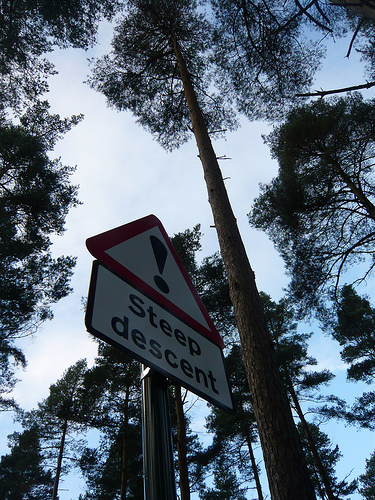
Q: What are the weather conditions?
A: It is clear.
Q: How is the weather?
A: It is clear.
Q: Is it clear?
A: Yes, it is clear.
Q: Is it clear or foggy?
A: It is clear.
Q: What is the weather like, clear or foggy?
A: It is clear.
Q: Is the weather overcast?
A: No, it is clear.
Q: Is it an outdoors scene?
A: Yes, it is outdoors.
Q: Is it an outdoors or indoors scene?
A: It is outdoors.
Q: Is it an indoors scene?
A: No, it is outdoors.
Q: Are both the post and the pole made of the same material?
A: Yes, both the post and the pole are made of metal.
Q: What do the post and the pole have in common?
A: The material, both the post and the pole are metallic.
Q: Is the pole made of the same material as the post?
A: Yes, both the pole and the post are made of metal.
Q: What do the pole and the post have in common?
A: The material, both the pole and the post are metallic.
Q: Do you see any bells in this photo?
A: No, there are no bells.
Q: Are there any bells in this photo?
A: No, there are no bells.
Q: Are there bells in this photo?
A: No, there are no bells.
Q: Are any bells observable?
A: No, there are no bells.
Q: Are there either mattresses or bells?
A: No, there are no bells or mattresses.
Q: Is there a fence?
A: No, there are no fences.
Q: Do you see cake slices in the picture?
A: No, there are no cake slices.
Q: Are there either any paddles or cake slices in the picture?
A: No, there are no cake slices or paddles.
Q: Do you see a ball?
A: No, there are no balls.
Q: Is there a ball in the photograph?
A: No, there are no balls.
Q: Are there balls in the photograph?
A: No, there are no balls.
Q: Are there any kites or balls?
A: No, there are no balls or kites.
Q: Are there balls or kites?
A: No, there are no balls or kites.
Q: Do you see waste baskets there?
A: No, there are no waste baskets.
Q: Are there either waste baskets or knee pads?
A: No, there are no waste baskets or knee pads.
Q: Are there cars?
A: No, there are no cars.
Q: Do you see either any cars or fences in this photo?
A: No, there are no cars or fences.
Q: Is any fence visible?
A: No, there are no fences.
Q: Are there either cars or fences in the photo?
A: No, there are no fences or cars.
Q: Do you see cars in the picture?
A: No, there are no cars.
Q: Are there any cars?
A: No, there are no cars.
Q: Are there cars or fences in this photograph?
A: No, there are no cars or fences.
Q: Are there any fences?
A: No, there are no fences.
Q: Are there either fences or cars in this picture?
A: No, there are no fences or cars.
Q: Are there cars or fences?
A: No, there are no fences or cars.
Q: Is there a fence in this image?
A: No, there are no fences.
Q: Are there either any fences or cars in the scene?
A: No, there are no fences or cars.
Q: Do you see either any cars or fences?
A: No, there are no cars or fences.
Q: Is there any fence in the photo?
A: No, there are no fences.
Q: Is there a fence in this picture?
A: No, there are no fences.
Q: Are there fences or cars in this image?
A: No, there are no fences or cars.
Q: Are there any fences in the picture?
A: No, there are no fences.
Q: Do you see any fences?
A: No, there are no fences.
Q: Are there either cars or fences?
A: No, there are no fences or cars.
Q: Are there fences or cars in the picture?
A: No, there are no fences or cars.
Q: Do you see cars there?
A: No, there are no cars.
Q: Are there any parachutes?
A: No, there are no parachutes.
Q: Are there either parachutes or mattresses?
A: No, there are no parachutes or mattresses.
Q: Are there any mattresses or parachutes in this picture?
A: No, there are no parachutes or mattresses.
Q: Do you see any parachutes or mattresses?
A: No, there are no parachutes or mattresses.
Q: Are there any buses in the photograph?
A: No, there are no buses.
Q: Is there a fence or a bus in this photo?
A: No, there are no buses or fences.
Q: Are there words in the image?
A: Yes, there are words.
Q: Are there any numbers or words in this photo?
A: Yes, there are words.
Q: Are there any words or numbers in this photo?
A: Yes, there are words.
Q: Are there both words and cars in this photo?
A: No, there are words but no cars.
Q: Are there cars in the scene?
A: No, there are no cars.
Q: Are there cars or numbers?
A: No, there are no cars or numbers.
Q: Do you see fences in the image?
A: No, there are no fences.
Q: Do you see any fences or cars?
A: No, there are no fences or cars.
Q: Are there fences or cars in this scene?
A: No, there are no fences or cars.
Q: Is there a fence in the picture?
A: No, there are no fences.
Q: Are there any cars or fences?
A: No, there are no fences or cars.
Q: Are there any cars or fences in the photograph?
A: No, there are no cars or fences.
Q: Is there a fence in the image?
A: No, there are no fences.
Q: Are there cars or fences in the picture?
A: No, there are no fences or cars.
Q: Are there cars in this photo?
A: No, there are no cars.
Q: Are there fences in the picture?
A: No, there are no fences.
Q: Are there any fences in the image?
A: No, there are no fences.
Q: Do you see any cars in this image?
A: No, there are no cars.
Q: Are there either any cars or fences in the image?
A: No, there are no cars or fences.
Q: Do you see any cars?
A: No, there are no cars.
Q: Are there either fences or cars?
A: No, there are no cars or fences.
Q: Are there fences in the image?
A: No, there are no fences.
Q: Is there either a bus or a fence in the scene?
A: No, there are no fences or buses.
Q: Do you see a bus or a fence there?
A: No, there are no fences or buses.